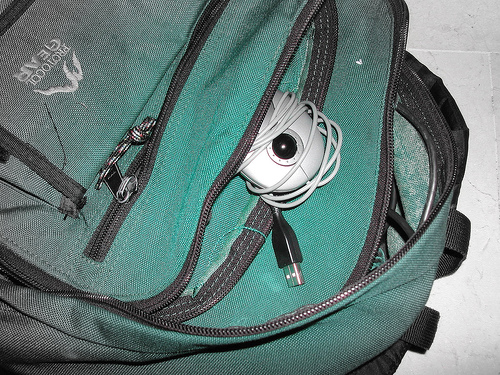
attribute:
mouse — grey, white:
[242, 97, 347, 289]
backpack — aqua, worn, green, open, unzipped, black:
[4, 1, 474, 374]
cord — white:
[243, 88, 338, 283]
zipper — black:
[79, 6, 228, 255]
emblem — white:
[14, 35, 83, 101]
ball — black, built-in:
[273, 130, 295, 160]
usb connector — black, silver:
[271, 219, 310, 288]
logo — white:
[14, 34, 83, 103]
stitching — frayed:
[209, 212, 266, 290]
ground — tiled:
[408, 4, 492, 374]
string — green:
[198, 225, 271, 270]